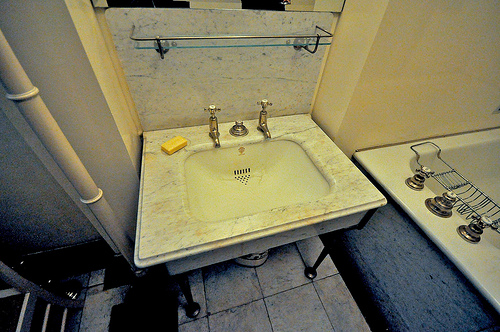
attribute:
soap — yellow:
[162, 137, 188, 152]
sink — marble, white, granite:
[133, 115, 386, 268]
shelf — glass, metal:
[133, 28, 334, 57]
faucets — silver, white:
[407, 164, 493, 247]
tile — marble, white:
[205, 278, 335, 331]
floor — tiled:
[85, 233, 379, 330]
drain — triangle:
[232, 163, 256, 189]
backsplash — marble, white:
[105, 8, 336, 129]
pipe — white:
[0, 37, 144, 279]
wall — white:
[342, 0, 499, 155]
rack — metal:
[412, 144, 499, 218]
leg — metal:
[302, 229, 353, 284]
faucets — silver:
[199, 101, 277, 150]